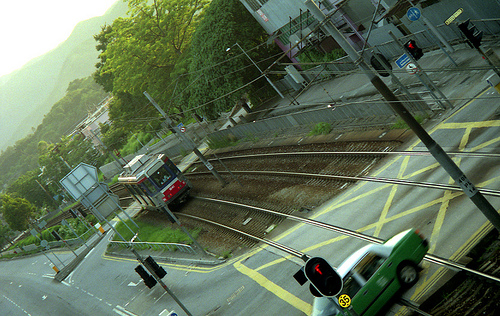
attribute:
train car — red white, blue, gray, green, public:
[117, 154, 193, 214]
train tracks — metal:
[192, 193, 304, 259]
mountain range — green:
[8, 29, 98, 129]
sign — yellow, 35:
[337, 292, 356, 311]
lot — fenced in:
[282, 25, 452, 125]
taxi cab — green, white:
[298, 225, 437, 314]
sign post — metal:
[124, 237, 190, 315]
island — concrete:
[53, 229, 110, 283]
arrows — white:
[3, 280, 53, 308]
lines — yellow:
[342, 151, 444, 234]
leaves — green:
[107, 7, 191, 83]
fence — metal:
[205, 98, 430, 146]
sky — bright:
[6, 4, 47, 53]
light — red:
[407, 39, 415, 50]